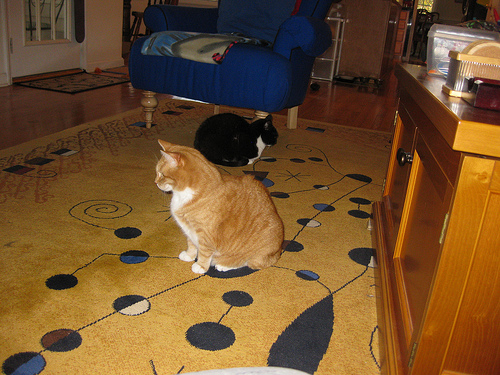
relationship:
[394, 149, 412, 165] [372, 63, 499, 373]
knobs on cabinet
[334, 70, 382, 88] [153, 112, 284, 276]
feed and water bowls for cats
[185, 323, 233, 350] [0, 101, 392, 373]
tound design on carpet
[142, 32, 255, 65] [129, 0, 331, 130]
blanket on chair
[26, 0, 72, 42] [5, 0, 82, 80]
window panels on door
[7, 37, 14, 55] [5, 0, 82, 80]
hinge on door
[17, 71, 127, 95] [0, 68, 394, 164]
mat on floor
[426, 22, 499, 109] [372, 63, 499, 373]
items on cabinet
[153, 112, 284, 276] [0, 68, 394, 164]
cats sitting on floor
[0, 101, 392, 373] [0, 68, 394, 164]
carpet covering floor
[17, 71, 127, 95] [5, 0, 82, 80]
mat in front of door